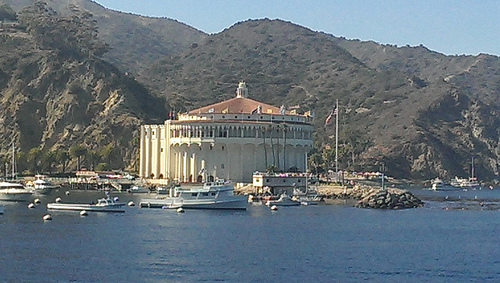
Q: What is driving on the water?
A: A boat.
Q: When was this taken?
A: During the day.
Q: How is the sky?
A: Clear.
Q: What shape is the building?
A: Round.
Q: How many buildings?
A: One.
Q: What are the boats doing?
A: Floating.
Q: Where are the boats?
A: In water.